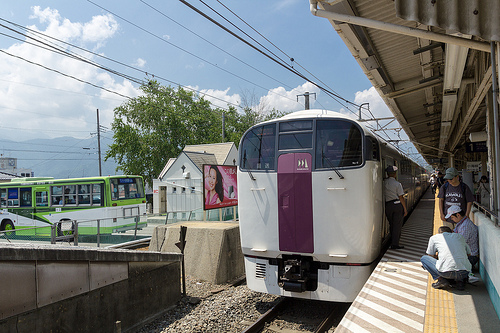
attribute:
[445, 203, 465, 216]
hat — white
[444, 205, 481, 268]
man — bending down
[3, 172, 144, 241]
bus — green, white, lime green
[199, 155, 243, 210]
billboard — wooden, advertisement, pink, red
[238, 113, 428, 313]
train — white, red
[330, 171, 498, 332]
platform — white, red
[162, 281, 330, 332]
gravel — gray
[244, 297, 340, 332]
train rails — metal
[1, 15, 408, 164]
clouds — fluffy, white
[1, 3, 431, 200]
sky — blue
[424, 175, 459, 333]
stripe — yellow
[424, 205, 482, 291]
men — kneeling down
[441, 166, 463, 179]
hat — green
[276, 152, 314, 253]
door — red, purple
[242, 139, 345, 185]
windshield wiper — black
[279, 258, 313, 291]
connector — black, metal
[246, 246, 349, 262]
handle bar — white